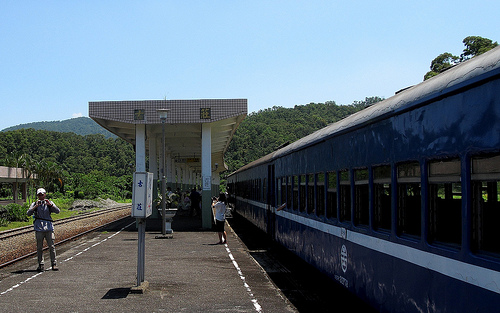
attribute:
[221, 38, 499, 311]
train — blue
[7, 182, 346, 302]
platform — black, asphalt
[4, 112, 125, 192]
mountain — covered, distant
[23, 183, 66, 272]
man — standing, taking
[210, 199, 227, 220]
shirt — white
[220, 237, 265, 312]
line — white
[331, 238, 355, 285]
insignia — white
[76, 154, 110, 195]
trees — distant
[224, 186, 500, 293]
stripe — white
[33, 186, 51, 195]
cap — white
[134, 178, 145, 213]
letters — chinese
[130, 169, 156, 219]
box — white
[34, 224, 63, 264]
pants — tan